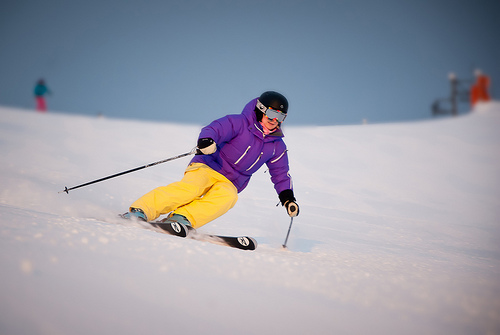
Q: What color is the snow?
A: White.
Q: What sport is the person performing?
A: Skiing.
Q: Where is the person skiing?
A: On a ski slope.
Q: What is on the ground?
A: Snow.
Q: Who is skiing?
A: A person in yellow snow pants.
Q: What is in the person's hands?
A: Ski poles.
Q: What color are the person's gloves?
A: Black and white.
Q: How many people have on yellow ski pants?
A: One.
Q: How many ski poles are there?
A: Two.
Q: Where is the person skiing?
A: Downhill.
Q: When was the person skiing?
A: During daylight hours.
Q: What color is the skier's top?
A: Purple.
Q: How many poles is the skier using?
A: Two.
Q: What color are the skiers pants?
A: Yellow.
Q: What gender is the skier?
A: Female.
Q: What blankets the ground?
A: Snow.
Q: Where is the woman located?
A: Ski slope.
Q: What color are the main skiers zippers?
A: White.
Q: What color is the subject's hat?
A: Black.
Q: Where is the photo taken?
A: On a ski slope.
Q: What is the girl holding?
A: Trekking poles.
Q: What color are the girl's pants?
A: Yellow.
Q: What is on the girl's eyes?
A: Goggles.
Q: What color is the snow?
A: White.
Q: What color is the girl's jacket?
A: Purple.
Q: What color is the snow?
A: White.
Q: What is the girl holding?
A: Trekking poles.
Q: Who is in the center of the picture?
A: A skier.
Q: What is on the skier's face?
A: A pair of goggles.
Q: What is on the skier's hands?
A: Gloves.